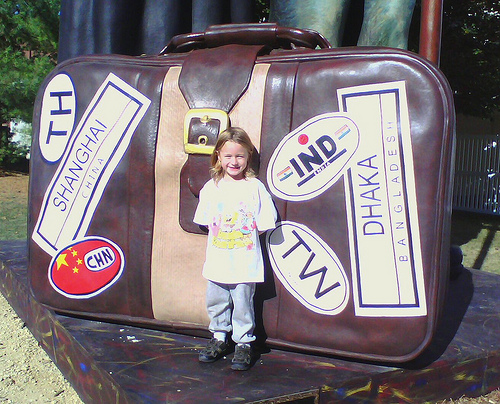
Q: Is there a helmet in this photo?
A: No, there are no helmets.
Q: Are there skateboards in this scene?
A: No, there are no skateboards.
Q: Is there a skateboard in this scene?
A: No, there are no skateboards.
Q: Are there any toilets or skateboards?
A: No, there are no skateboards or toilets.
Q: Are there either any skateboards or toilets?
A: No, there are no skateboards or toilets.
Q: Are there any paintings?
A: No, there are no paintings.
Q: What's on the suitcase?
A: The sticker is on the suitcase.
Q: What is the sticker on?
A: The sticker is on the suitcase.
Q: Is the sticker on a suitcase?
A: Yes, the sticker is on a suitcase.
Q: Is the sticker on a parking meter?
A: No, the sticker is on a suitcase.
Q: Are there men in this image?
A: No, there are no men.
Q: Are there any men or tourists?
A: No, there are no men or tourists.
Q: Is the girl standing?
A: Yes, the girl is standing.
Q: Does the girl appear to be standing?
A: Yes, the girl is standing.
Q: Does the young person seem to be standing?
A: Yes, the girl is standing.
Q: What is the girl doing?
A: The girl is standing.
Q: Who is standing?
A: The girl is standing.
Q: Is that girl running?
A: No, the girl is standing.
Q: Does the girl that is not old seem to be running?
A: No, the girl is standing.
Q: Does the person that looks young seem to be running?
A: No, the girl is standing.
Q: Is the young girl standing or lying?
A: The girl is standing.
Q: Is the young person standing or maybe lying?
A: The girl is standing.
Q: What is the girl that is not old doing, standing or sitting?
A: The girl is standing.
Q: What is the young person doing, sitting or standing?
A: The girl is standing.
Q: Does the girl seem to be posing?
A: Yes, the girl is posing.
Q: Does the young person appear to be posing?
A: Yes, the girl is posing.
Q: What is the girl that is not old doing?
A: The girl is posing.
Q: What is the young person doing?
A: The girl is posing.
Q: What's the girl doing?
A: The girl is posing.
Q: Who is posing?
A: The girl is posing.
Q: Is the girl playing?
A: No, the girl is posing.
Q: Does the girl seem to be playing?
A: No, the girl is posing.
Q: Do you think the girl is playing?
A: No, the girl is posing.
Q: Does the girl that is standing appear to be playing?
A: No, the girl is posing.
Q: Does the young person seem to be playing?
A: No, the girl is posing.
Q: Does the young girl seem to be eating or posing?
A: The girl is posing.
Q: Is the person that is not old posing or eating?
A: The girl is posing.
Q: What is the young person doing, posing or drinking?
A: The girl is posing.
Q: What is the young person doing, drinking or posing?
A: The girl is posing.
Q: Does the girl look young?
A: Yes, the girl is young.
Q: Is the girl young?
A: Yes, the girl is young.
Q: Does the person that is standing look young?
A: Yes, the girl is young.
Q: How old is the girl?
A: The girl is young.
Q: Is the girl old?
A: No, the girl is young.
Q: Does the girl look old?
A: No, the girl is young.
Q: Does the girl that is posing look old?
A: No, the girl is young.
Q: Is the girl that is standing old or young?
A: The girl is young.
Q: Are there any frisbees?
A: No, there are no frisbees.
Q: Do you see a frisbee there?
A: No, there are no frisbees.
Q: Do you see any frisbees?
A: No, there are no frisbees.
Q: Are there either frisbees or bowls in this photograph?
A: No, there are no frisbees or bowls.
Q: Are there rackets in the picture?
A: No, there are no rackets.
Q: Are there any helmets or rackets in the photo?
A: No, there are no rackets or helmets.